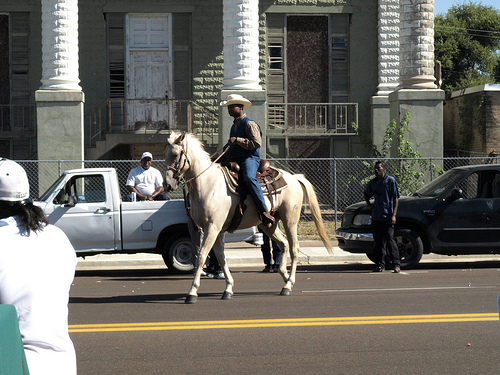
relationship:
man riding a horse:
[215, 89, 279, 230] [158, 124, 335, 305]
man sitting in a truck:
[124, 146, 168, 203] [28, 164, 267, 277]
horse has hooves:
[158, 124, 335, 305] [183, 287, 295, 304]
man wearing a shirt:
[124, 146, 168, 203] [125, 162, 165, 195]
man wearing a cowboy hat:
[215, 89, 279, 230] [217, 93, 252, 106]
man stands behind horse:
[362, 157, 403, 272] [158, 124, 335, 305]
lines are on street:
[69, 308, 500, 335] [69, 265, 500, 375]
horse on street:
[158, 124, 335, 305] [69, 265, 500, 375]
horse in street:
[158, 124, 335, 305] [69, 265, 500, 375]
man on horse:
[215, 89, 279, 230] [158, 124, 335, 305]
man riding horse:
[215, 89, 279, 230] [158, 124, 335, 305]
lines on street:
[69, 308, 500, 335] [69, 265, 500, 375]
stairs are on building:
[79, 100, 129, 166] [1, 1, 446, 207]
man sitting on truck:
[215, 89, 279, 230] [28, 164, 267, 277]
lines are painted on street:
[69, 308, 500, 335] [69, 265, 500, 375]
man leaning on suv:
[362, 157, 403, 272] [332, 161, 499, 273]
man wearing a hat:
[124, 146, 168, 203] [138, 149, 157, 161]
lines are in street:
[69, 308, 500, 335] [69, 265, 500, 375]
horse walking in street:
[158, 124, 335, 305] [69, 265, 500, 375]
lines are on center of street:
[69, 308, 500, 335] [69, 265, 500, 375]